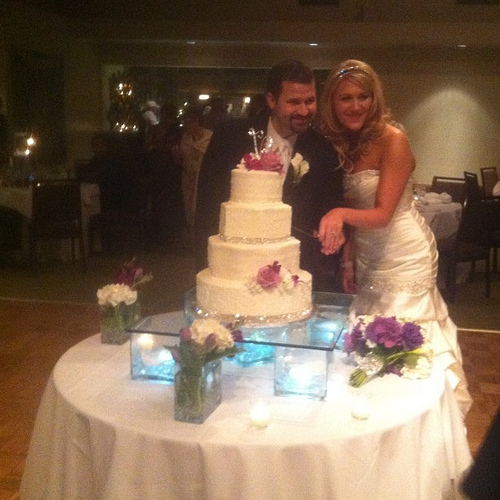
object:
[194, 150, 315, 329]
wedding cake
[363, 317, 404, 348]
flowers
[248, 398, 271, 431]
candles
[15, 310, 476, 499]
table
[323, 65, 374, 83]
head bnad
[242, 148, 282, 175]
flowers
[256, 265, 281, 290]
flowers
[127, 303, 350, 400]
glass cake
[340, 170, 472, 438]
wedding dress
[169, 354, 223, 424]
vase